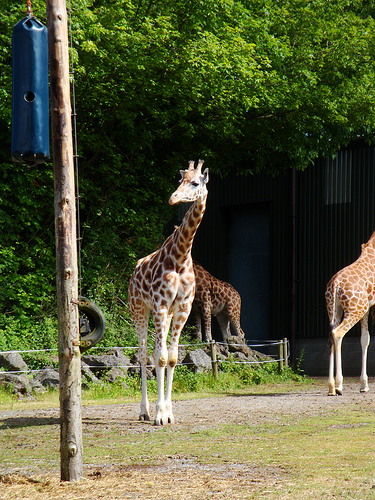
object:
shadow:
[0, 417, 70, 429]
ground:
[0, 426, 375, 500]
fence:
[0, 337, 290, 376]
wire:
[217, 340, 282, 347]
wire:
[217, 358, 283, 364]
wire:
[0, 347, 61, 355]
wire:
[82, 364, 140, 369]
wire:
[2, 367, 57, 377]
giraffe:
[193, 257, 245, 342]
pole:
[51, 4, 82, 484]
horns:
[197, 159, 205, 170]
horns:
[187, 160, 195, 168]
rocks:
[178, 335, 278, 372]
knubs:
[176, 156, 215, 173]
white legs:
[153, 309, 192, 405]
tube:
[78, 296, 106, 351]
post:
[55, 199, 78, 278]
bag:
[11, 15, 48, 155]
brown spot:
[157, 357, 166, 368]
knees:
[158, 355, 177, 367]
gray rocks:
[80, 346, 137, 390]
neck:
[170, 198, 207, 255]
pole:
[57, 336, 84, 479]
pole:
[43, 0, 89, 478]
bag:
[10, 12, 50, 160]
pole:
[44, 3, 86, 484]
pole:
[47, 29, 84, 281]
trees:
[109, 52, 289, 151]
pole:
[47, 5, 68, 114]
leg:
[166, 309, 190, 401]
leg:
[155, 307, 168, 397]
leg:
[132, 316, 150, 398]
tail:
[330, 281, 337, 327]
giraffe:
[325, 230, 375, 396]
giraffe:
[127, 158, 209, 426]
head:
[168, 159, 210, 206]